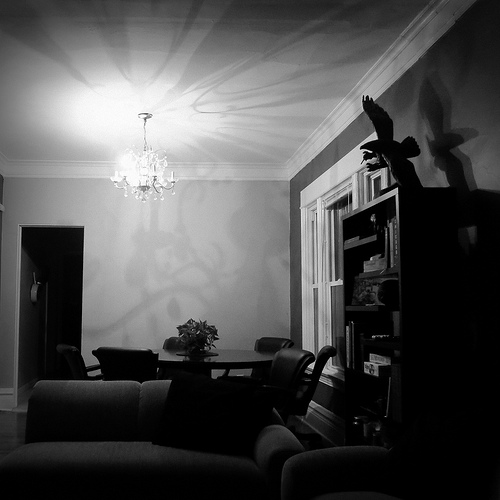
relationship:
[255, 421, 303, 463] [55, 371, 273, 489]
arm of couch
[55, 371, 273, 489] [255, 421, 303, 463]
couch without arm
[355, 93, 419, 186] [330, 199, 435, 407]
statue on book shelf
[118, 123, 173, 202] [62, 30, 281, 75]
light hanging from ceiling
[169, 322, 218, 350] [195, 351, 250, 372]
flowers on table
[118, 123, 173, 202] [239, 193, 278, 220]
light on wall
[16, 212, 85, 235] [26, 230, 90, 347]
entryway to room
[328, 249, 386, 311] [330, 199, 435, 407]
items on book shelf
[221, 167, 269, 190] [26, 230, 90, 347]
molding around room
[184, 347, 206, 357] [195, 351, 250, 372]
pot on table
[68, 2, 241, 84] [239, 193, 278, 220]
reflection on wall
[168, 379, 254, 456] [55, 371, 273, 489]
pillow on couch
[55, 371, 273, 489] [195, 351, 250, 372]
couch in front of table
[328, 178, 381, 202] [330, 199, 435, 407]
books on book shelf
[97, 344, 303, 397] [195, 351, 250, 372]
chairs around table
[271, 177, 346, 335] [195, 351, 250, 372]
window next to table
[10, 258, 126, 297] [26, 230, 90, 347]
doorway to room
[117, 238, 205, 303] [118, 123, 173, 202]
shadow from light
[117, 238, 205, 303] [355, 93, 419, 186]
shadow of statue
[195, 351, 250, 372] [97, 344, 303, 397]
table with chairs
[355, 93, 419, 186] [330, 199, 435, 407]
statue on top of book shelf